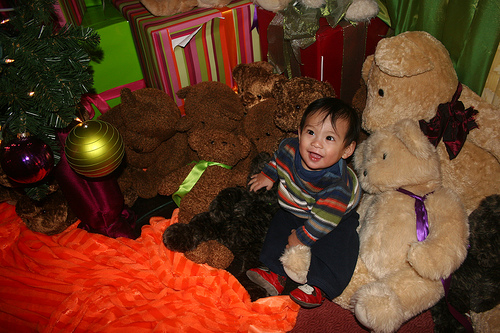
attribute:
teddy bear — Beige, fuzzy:
[357, 29, 498, 329]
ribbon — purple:
[395, 185, 448, 243]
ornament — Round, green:
[57, 112, 140, 197]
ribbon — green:
[174, 162, 235, 202]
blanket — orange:
[5, 201, 330, 331]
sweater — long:
[261, 138, 354, 246]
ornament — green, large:
[66, 118, 126, 179]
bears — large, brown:
[100, 26, 493, 329]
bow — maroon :
[417, 78, 479, 168]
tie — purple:
[406, 183, 431, 239]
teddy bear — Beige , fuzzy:
[279, 115, 470, 330]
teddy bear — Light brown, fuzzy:
[359, 28, 499, 215]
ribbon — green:
[173, 160, 228, 206]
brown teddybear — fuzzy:
[153, 125, 249, 266]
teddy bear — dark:
[158, 154, 279, 300]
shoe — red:
[289, 280, 323, 310]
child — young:
[248, 93, 360, 305]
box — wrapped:
[278, 10, 370, 92]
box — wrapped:
[138, 10, 275, 87]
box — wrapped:
[71, 2, 162, 108]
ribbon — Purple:
[385, 185, 452, 242]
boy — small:
[231, 84, 404, 314]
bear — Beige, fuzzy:
[328, 123, 498, 310]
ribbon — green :
[148, 137, 253, 188]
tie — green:
[166, 158, 230, 205]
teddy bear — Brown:
[160, 125, 248, 259]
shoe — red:
[243, 266, 285, 295]